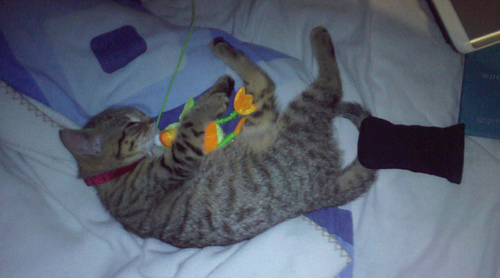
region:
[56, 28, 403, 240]
a grey and black cat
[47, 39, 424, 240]
a sleeping cat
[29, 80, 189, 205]
a cat with a red collar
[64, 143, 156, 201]
a red collar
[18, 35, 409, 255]
a cat sleeping on a bed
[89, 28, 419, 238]
a cat hugging a toy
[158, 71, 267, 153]
a toy being hugged by a cat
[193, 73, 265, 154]
an orange flower on a toy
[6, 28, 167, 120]
a blue and white bedspread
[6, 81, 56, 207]
a white bedspread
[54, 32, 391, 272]
this cat looks like my cat!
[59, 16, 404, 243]
the cat is tiger striped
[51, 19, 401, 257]
he is a tabby cat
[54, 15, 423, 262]
the cat has a red collar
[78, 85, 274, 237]
he is playing with a toy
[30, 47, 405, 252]
the cat is lying on a white & blue blanket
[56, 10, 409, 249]
the kitty appears to be a baby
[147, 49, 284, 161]
the toy is orange & green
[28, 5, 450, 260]
what an adorable cat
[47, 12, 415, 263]
he appears to be nearly asleep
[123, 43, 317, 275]
A cat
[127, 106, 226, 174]
A cat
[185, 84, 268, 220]
A cat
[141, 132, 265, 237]
A cat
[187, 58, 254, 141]
A cat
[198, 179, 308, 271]
A cat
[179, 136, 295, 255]
A cat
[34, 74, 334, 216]
cat playing with toy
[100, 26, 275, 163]
cat toy is on a stick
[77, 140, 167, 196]
cat is wearing a red collar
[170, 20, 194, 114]
stick is green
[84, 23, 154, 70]
blue square on the bed cover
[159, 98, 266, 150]
fish toy is blue, orange and green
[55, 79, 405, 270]
cat lying on the bed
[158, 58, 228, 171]
cat's arms around the toy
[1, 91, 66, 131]
stitching on the bed cover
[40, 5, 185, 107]
bed cover is different colors of blue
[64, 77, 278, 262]
The cat is laying down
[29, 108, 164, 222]
The cat has a collar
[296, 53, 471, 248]
The cat has a tail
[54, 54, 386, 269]
The cat is a tiger cat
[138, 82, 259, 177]
The cat has a toy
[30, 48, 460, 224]
The cat is laying on a blue and white blanket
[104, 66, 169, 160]
The cat's eyes are slightly open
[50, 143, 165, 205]
The cat has on a maroon collar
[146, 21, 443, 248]
The cat has 4 legs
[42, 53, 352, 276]
The cat is gray and black